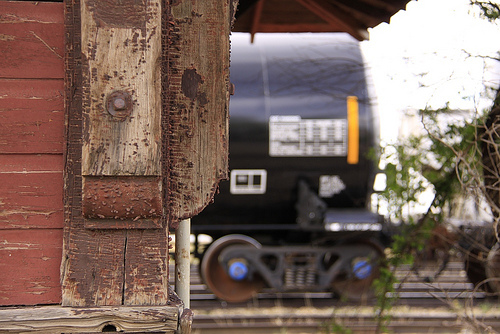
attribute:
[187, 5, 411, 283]
tanker — black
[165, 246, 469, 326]
track — railroad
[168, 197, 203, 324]
pipe — old, gray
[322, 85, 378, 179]
line — yellow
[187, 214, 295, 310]
wheel — train, black, metal, locomotive, blue, rusted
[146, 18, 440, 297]
train — station, passing, wooden, track, black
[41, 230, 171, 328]
piece — wood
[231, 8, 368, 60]
support — red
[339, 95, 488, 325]
leave — hanging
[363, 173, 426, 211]
light — bright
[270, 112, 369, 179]
panel — white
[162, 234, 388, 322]
platform — square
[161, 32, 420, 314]
locomotive — behind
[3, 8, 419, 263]
building — wall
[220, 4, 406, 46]
underhand — structure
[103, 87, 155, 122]
bolt — rusted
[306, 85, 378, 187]
sticker — yellow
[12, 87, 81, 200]
paint — red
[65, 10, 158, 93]
wood — old, peeling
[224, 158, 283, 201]
sign — white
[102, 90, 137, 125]
screw — metal